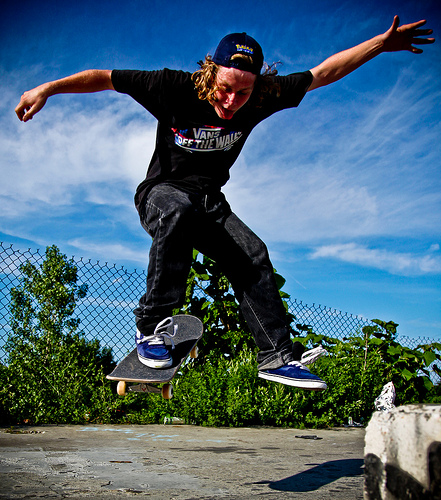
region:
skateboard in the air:
[96, 307, 208, 400]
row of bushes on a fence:
[2, 243, 439, 434]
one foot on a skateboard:
[121, 317, 174, 371]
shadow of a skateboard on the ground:
[263, 443, 365, 491]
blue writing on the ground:
[79, 421, 225, 450]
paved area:
[0, 414, 388, 498]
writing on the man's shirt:
[170, 122, 242, 156]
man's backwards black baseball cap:
[209, 27, 269, 76]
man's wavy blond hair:
[192, 54, 219, 105]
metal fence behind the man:
[0, 232, 439, 409]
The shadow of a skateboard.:
[267, 455, 364, 495]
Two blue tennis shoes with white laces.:
[135, 322, 329, 395]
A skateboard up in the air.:
[104, 312, 206, 400]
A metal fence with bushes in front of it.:
[0, 241, 440, 419]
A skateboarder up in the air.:
[16, 12, 436, 404]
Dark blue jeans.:
[131, 185, 308, 372]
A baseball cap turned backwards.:
[209, 29, 264, 75]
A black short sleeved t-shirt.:
[111, 66, 311, 206]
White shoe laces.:
[297, 342, 328, 365]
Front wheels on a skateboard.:
[113, 377, 176, 400]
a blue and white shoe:
[244, 340, 361, 391]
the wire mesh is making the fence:
[63, 288, 127, 335]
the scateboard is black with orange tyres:
[91, 315, 193, 399]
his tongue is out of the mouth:
[177, 33, 280, 151]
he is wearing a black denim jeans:
[138, 196, 277, 342]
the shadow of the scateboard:
[251, 447, 362, 498]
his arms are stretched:
[2, 0, 435, 268]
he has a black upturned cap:
[185, 28, 282, 78]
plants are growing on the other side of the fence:
[2, 307, 110, 413]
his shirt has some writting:
[167, 125, 263, 197]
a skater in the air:
[10, 2, 434, 397]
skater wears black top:
[8, 0, 440, 393]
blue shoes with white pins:
[121, 317, 330, 397]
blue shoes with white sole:
[122, 320, 334, 392]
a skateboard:
[92, 306, 216, 425]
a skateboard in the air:
[99, 323, 204, 408]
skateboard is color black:
[100, 323, 206, 405]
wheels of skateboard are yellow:
[96, 346, 198, 403]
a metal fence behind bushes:
[6, 236, 410, 420]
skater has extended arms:
[12, 0, 437, 263]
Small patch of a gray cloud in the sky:
[285, 186, 307, 206]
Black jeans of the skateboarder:
[158, 210, 238, 320]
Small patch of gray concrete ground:
[118, 453, 153, 485]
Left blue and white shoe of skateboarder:
[283, 366, 305, 385]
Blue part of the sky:
[391, 300, 406, 313]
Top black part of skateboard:
[128, 364, 141, 377]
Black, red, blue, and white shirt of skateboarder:
[158, 130, 223, 175]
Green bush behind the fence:
[197, 405, 226, 425]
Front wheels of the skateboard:
[109, 382, 175, 401]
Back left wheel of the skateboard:
[190, 348, 200, 360]